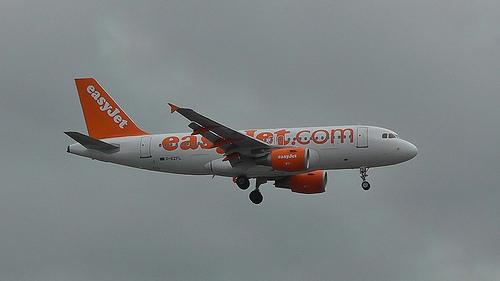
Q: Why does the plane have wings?
A: To fly.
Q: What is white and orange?
A: Plane.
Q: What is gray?
A: Sky.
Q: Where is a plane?
A: In the sky.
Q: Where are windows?
A: On a plane.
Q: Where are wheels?
A: Under the plane.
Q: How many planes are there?
A: One.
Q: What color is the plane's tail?
A: Orange.